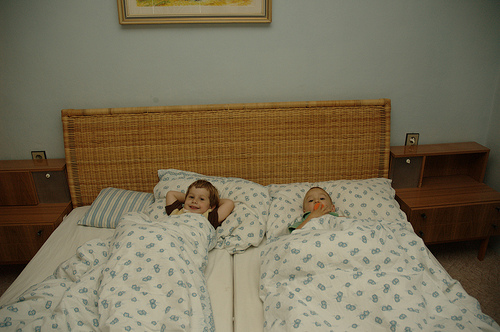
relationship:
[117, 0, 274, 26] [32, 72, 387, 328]
frame above bed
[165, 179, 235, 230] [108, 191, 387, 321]
boy under comforters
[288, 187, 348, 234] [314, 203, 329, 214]
baby holding binky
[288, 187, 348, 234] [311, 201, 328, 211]
baby has pacifier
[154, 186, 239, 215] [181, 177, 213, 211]
arms behind head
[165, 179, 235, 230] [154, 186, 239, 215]
boy has arms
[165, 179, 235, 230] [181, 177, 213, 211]
boy has head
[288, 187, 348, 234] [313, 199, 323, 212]
baby sucking pacifier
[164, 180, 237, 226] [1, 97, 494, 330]
boy lying down bed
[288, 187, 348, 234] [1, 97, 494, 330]
baby lying down bed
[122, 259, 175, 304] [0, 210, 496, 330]
designs on blanket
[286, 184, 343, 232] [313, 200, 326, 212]
baby has pacifier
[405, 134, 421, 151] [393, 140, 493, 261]
picture on table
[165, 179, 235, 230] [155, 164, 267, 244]
boy laying on pillow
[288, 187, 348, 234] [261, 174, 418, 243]
baby laying on pillow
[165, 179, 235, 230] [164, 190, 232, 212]
boy on arms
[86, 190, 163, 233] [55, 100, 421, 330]
pillow on bed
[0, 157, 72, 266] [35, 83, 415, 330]
night stand near bed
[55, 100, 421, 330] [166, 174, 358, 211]
bed underneath kids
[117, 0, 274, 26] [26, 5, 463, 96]
frame on wall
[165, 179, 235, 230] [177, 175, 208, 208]
boy with hands behind head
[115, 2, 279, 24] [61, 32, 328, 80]
frame on wall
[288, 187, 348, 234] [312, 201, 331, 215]
baby with binky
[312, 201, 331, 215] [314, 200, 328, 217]
binky in mouth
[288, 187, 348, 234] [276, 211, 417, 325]
baby under sheets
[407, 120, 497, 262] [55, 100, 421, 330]
cupboards next to bed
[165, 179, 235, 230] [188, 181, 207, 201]
boy with head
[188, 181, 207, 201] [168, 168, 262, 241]
head on pillow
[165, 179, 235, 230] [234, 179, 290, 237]
boy on pillow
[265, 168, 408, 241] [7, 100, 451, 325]
pillow on a bed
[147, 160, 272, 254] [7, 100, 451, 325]
pillow on a bed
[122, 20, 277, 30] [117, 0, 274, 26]
edge of a frame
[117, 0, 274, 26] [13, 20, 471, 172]
frame on the wall